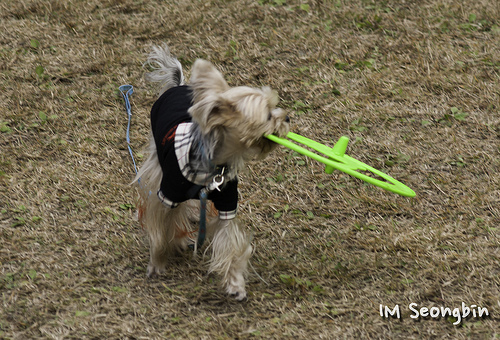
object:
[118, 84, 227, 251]
leash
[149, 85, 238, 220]
sweater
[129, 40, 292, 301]
dog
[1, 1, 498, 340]
grass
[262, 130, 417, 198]
toy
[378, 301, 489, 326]
lettering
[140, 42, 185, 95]
tail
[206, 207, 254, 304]
leg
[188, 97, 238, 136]
ears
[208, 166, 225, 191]
clip